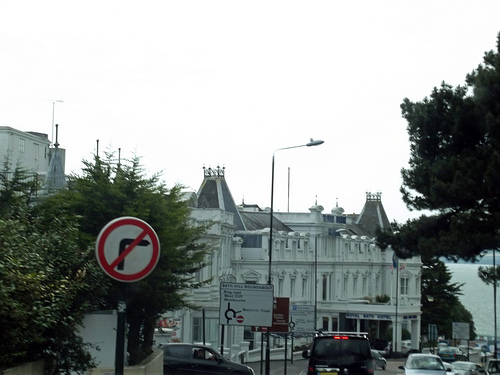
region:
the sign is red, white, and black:
[76, 208, 188, 298]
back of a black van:
[294, 327, 407, 374]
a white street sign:
[204, 270, 288, 337]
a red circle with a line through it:
[84, 202, 171, 284]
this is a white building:
[182, 150, 441, 361]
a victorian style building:
[185, 157, 432, 357]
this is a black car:
[148, 330, 263, 374]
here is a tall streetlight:
[263, 113, 333, 373]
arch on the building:
[272, 235, 282, 264]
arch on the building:
[282, 237, 297, 261]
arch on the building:
[299, 238, 312, 263]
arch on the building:
[338, 240, 353, 256]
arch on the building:
[350, 244, 362, 261]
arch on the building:
[360, 272, 371, 294]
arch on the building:
[339, 273, 349, 294]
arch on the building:
[300, 278, 309, 296]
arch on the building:
[289, 274, 296, 299]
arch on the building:
[277, 277, 292, 299]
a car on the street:
[298, 329, 376, 374]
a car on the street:
[153, 338, 253, 374]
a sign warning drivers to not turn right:
[90, 214, 162, 289]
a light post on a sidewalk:
[262, 138, 326, 371]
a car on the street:
[397, 352, 449, 374]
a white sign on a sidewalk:
[215, 278, 272, 373]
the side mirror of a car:
[297, 349, 310, 360]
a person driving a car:
[194, 348, 214, 360]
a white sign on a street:
[449, 319, 470, 360]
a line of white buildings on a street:
[0, 122, 422, 374]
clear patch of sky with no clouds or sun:
[6, 3, 462, 79]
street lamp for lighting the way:
[270, 137, 326, 152]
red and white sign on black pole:
[98, 217, 158, 372]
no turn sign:
[97, 218, 159, 280]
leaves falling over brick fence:
[1, 283, 93, 372]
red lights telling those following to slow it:
[332, 333, 349, 341]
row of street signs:
[215, 280, 290, 374]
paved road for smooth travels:
[379, 365, 396, 372]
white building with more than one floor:
[327, 235, 387, 287]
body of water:
[464, 287, 488, 305]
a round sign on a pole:
[98, 215, 163, 294]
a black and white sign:
[213, 277, 279, 327]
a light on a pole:
[258, 133, 328, 281]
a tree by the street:
[376, 30, 498, 267]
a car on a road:
[303, 326, 375, 373]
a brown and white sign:
[273, 294, 293, 334]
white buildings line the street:
[223, 183, 426, 350]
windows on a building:
[279, 268, 387, 296]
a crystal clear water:
[454, 258, 499, 335]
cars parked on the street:
[394, 350, 456, 369]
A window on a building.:
[276, 270, 287, 294]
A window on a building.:
[299, 271, 311, 298]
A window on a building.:
[301, 235, 310, 257]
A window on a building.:
[289, 240, 295, 260]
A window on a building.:
[278, 239, 287, 260]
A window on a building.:
[343, 270, 350, 297]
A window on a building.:
[352, 273, 354, 291]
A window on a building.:
[358, 272, 368, 293]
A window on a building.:
[399, 269, 413, 293]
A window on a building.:
[190, 318, 214, 342]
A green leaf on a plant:
[20, 236, 22, 237]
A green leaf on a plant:
[439, 163, 442, 165]